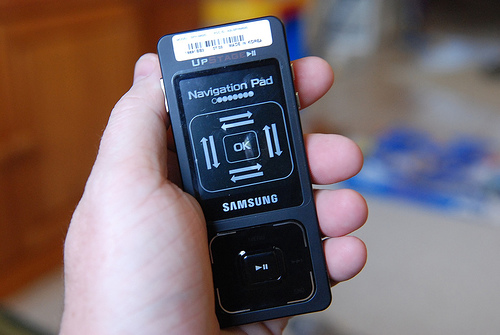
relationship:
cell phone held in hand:
[156, 12, 331, 329] [59, 53, 369, 333]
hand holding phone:
[59, 53, 369, 333] [140, 12, 417, 329]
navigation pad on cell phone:
[187, 72, 274, 102] [156, 12, 331, 329]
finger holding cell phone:
[286, 38, 386, 293] [156, 12, 331, 329]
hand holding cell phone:
[59, 53, 369, 333] [155, 34, 291, 216]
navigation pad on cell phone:
[187, 72, 285, 105] [156, 12, 331, 329]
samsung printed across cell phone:
[223, 194, 278, 212] [156, 12, 331, 329]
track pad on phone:
[192, 95, 294, 196] [150, 20, 348, 332]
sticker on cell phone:
[174, 19, 272, 64] [156, 12, 331, 329]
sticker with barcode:
[174, 19, 272, 64] [206, 37, 230, 48]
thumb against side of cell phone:
[109, 35, 179, 157] [156, 12, 331, 329]